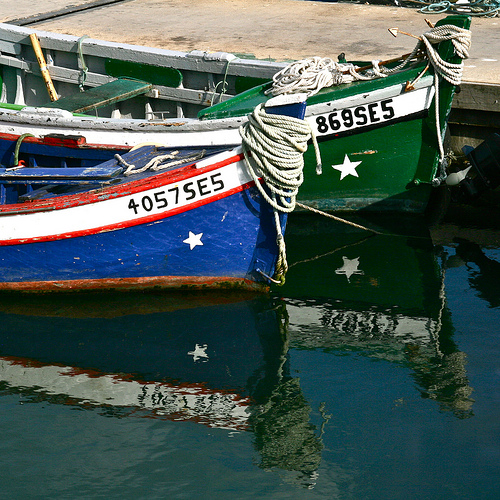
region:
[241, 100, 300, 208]
rope wrapped around the stern of a boar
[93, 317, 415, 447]
reflections on the surface of the water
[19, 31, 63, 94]
the handle of an oar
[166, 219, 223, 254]
a white star on the boat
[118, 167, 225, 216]
numbers on the side of the boat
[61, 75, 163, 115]
a bench on the boat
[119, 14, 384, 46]
a paved pier next to the river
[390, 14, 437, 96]
a rusted weather vane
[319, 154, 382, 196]
a white star on a green boat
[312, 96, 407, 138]
black numbers on a green and white boat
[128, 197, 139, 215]
The number 4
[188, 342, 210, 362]
Reflection of a white star in the water.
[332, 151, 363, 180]
White star on a green boat.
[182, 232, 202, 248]
White star on a blue boat.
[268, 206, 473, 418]
Reflection of green boat in the water.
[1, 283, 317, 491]
Reflection of blue boat in the water.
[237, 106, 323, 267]
Rope on a boat.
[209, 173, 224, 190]
The number 5 on a boat.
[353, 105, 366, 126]
Letter S on a boat.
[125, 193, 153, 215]
Number 40 on the side of a boat.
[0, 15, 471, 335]
two boats next to a dock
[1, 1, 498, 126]
dock is in the water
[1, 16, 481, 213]
green boat is closest to the dock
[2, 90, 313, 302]
boat is red, white & blue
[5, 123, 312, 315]
boat is next to green boat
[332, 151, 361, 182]
green boat has white star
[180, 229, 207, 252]
blue boat has white star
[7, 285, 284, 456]
blue boat casts reflection in water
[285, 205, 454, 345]
green boat casts reflection in water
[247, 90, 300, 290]
rope is wrapped around front of blue boat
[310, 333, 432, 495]
this is the water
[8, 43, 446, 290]
these are two boats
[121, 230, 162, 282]
the boat is blue in color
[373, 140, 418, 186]
the boat is green in color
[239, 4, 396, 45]
this is the dock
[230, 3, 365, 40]
the dock is made of wood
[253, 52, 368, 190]
these are some ropes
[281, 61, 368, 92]
the ropes are on the boat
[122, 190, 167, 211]
these are numbers on the white strip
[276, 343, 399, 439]
the water is still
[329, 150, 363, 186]
a white star on the boat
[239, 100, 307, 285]
white rope on the boat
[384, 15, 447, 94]
an anchor on the boat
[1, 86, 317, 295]
a red, white and blue boat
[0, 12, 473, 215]
a green and white boat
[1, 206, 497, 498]
dark water under the boats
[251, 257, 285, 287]
a hood on the boat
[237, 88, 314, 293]
the bow of the blue boat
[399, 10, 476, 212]
the bow of the green boat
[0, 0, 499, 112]
a gray cement walkway